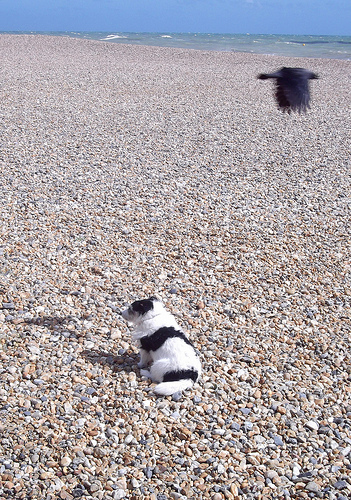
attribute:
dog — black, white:
[111, 294, 202, 392]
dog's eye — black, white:
[125, 307, 135, 316]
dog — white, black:
[111, 244, 221, 404]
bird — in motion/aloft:
[254, 70, 311, 120]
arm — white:
[128, 333, 149, 370]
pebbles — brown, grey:
[32, 408, 321, 492]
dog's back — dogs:
[141, 314, 205, 389]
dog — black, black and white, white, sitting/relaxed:
[120, 290, 201, 397]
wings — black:
[278, 68, 311, 113]